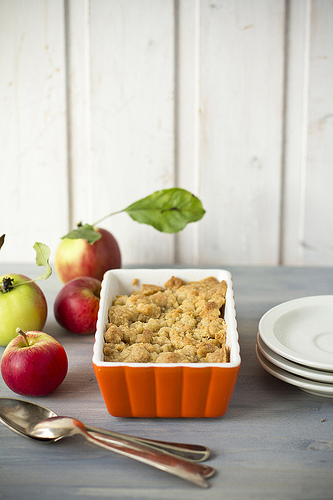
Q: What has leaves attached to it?
A: Apples.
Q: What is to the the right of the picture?
A: Plates.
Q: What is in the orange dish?
A: Casserole.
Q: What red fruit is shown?
A: Apples.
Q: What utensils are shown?
A: Spoons.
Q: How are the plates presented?
A: Stacked.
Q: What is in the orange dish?
A: Apple crumble.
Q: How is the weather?
A: Clear and sunny.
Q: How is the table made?
A: Of wood.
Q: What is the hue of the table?
A: Gray.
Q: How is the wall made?
A: Of wood.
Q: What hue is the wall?
A: Gray.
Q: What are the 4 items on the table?
A: Apples.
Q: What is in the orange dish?
A: Apple crisp.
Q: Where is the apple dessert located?
A: On table.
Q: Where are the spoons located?
A: Table.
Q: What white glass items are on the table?
A: Plates.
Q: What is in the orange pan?
A: Food.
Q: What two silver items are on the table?
A: Spoons.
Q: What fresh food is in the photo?
A: Fruit.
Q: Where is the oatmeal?
A: Bowl.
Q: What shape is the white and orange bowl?
A: Rectangle.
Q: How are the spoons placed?
A: On top of each other.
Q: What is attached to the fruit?
A: Leaves.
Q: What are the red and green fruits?
A: Apples.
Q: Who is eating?
A: No one.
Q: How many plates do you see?
A: 3.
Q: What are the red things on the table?
A: Apples.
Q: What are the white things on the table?
A: Plates.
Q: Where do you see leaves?
A: On the apples.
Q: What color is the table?
A: Grey.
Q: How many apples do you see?
A: 4.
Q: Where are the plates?
A: Next to the orange dish.